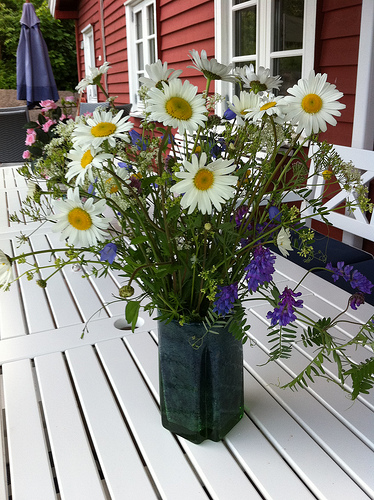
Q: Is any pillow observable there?
A: No, there are no pillows.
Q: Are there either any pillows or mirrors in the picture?
A: No, there are no pillows or mirrors.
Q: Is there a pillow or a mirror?
A: No, there are no pillows or mirrors.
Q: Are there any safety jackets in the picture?
A: No, there are no safety jackets.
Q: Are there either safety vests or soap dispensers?
A: No, there are no safety vests or soap dispensers.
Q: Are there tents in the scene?
A: No, there are no tents.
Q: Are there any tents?
A: No, there are no tents.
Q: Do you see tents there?
A: No, there are no tents.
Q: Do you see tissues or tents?
A: No, there are no tents or tissues.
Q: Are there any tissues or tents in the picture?
A: No, there are no tents or tissues.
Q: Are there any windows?
A: Yes, there is a window.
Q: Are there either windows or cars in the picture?
A: Yes, there is a window.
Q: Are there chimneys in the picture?
A: No, there are no chimneys.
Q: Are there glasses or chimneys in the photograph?
A: No, there are no chimneys or glasses.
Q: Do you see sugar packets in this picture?
A: No, there are no sugar packets.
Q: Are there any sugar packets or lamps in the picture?
A: No, there are no sugar packets or lamps.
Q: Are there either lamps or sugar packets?
A: No, there are no sugar packets or lamps.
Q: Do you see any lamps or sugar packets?
A: No, there are no sugar packets or lamps.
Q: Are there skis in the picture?
A: No, there are no skis.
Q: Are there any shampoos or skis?
A: No, there are no skis or shampoos.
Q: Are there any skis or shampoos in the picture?
A: No, there are no skis or shampoos.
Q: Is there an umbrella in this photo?
A: Yes, there is an umbrella.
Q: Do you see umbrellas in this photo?
A: Yes, there is an umbrella.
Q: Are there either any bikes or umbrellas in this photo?
A: Yes, there is an umbrella.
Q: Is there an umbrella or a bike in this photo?
A: Yes, there is an umbrella.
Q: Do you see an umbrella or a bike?
A: Yes, there is an umbrella.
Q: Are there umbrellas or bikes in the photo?
A: Yes, there is an umbrella.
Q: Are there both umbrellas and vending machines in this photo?
A: No, there is an umbrella but no vending machines.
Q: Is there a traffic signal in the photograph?
A: No, there are no traffic lights.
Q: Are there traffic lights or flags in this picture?
A: No, there are no traffic lights or flags.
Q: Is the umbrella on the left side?
A: Yes, the umbrella is on the left of the image.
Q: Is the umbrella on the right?
A: No, the umbrella is on the left of the image.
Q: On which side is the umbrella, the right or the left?
A: The umbrella is on the left of the image.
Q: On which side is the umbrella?
A: The umbrella is on the left of the image.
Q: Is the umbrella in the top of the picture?
A: Yes, the umbrella is in the top of the image.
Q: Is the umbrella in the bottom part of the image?
A: No, the umbrella is in the top of the image.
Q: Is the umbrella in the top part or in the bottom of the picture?
A: The umbrella is in the top of the image.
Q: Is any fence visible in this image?
A: No, there are no fences.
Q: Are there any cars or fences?
A: No, there are no fences or cars.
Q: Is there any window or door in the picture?
A: Yes, there is a window.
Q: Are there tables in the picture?
A: Yes, there is a table.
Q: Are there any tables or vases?
A: Yes, there is a table.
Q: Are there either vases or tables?
A: Yes, there is a table.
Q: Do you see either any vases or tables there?
A: Yes, there is a table.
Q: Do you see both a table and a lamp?
A: No, there is a table but no lamps.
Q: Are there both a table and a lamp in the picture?
A: No, there is a table but no lamps.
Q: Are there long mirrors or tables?
A: Yes, there is a long table.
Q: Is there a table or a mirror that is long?
A: Yes, the table is long.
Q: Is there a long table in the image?
A: Yes, there is a long table.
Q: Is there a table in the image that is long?
A: Yes, there is a table that is long.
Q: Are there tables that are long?
A: Yes, there is a table that is long.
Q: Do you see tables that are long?
A: Yes, there is a table that is long.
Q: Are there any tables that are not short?
A: Yes, there is a long table.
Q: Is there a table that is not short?
A: Yes, there is a long table.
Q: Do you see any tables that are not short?
A: Yes, there is a long table.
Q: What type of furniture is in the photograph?
A: The furniture is a table.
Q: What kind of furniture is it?
A: The piece of furniture is a table.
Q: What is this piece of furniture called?
A: This is a table.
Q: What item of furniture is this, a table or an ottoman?
A: This is a table.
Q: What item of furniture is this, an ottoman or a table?
A: This is a table.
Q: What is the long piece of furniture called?
A: The piece of furniture is a table.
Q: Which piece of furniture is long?
A: The piece of furniture is a table.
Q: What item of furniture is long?
A: The piece of furniture is a table.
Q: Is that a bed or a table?
A: That is a table.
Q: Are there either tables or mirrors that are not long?
A: No, there is a table but it is long.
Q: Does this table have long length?
A: Yes, the table is long.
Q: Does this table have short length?
A: No, the table is long.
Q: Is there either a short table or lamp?
A: No, there is a table but it is long.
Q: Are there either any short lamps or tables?
A: No, there is a table but it is long.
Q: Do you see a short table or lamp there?
A: No, there is a table but it is long.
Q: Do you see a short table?
A: No, there is a table but it is long.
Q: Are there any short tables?
A: No, there is a table but it is long.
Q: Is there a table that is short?
A: No, there is a table but it is long.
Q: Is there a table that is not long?
A: No, there is a table but it is long.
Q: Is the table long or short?
A: The table is long.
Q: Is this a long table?
A: Yes, this is a long table.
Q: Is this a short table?
A: No, this is a long table.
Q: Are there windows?
A: Yes, there is a window.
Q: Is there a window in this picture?
A: Yes, there is a window.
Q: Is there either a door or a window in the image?
A: Yes, there is a window.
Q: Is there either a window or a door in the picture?
A: Yes, there is a window.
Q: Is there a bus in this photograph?
A: No, there are no buses.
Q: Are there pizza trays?
A: No, there are no pizza trays.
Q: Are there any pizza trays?
A: No, there are no pizza trays.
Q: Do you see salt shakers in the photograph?
A: No, there are no salt shakers.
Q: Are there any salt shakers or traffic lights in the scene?
A: No, there are no salt shakers or traffic lights.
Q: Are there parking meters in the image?
A: No, there are no parking meters.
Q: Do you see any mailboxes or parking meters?
A: No, there are no parking meters or mailboxes.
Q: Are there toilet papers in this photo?
A: No, there are no toilet papers.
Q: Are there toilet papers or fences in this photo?
A: No, there are no toilet papers or fences.